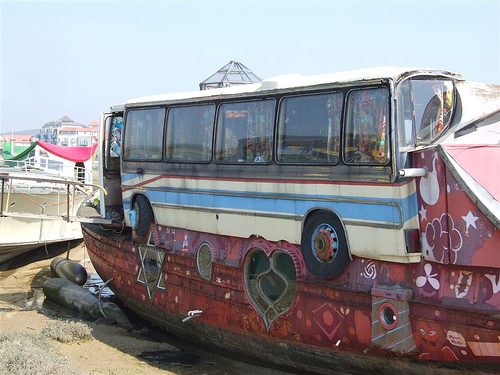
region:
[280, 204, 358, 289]
large black wheel on side of bus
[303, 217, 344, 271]
holes in black wheel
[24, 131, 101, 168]
pink roof on building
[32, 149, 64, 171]
small window in building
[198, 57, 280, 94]
glass dome on blue building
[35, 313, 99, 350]
small patch of bush on ground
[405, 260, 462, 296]
picture of white clover leaf on side of bus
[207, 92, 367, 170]
large clear windows in bus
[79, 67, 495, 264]
large blue and white bus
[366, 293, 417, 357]
round hole with red edge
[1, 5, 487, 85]
the sky is clear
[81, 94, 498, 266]
a bus is in the photo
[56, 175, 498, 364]
a boat is in the photo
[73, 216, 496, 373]
the boat is red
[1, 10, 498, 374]
the photo was taken outside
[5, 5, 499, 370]
the photo was taken during the day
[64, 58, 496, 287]
the bus is not moving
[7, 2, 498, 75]
the sky is blue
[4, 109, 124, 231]
buildings are in the photo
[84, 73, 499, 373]
the bus us on a boat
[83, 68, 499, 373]
the boat is morphed with a bus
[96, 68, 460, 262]
the bus is white and blue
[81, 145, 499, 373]
the boat is red with designs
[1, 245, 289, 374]
the boat is on the shore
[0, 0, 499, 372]
the scene takes place outdoors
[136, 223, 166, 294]
the boat has a star of david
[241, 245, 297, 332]
the boat has a heart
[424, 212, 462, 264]
the boat has a cloud design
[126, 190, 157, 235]
drivers side left front tire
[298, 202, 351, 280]
drivers side left rear tire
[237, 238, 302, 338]
heart shapes window in side of boat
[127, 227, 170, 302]
star shaped window in side of boat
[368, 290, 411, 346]
round window in side of boat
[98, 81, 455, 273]
bus built in to top of boat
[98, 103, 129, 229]
open door on side of bus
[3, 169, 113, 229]
walkway leading to open door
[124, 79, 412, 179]
windows down side of bus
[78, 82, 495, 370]
large custom made boat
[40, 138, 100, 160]
Red roof on building behind the bus.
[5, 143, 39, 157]
Green roof on the building behind the bus.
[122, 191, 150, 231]
Rear wheel of the bus.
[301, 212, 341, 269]
Front wheel of the bus.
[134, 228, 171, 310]
Jewish star design on the boat.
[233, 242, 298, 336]
Heart design on the boat.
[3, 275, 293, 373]
Sand that the boat is placed on.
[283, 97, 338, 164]
Window without a curtain.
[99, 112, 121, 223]
Open door of the bus.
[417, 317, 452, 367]
Character drawn on the boat with white eyes.